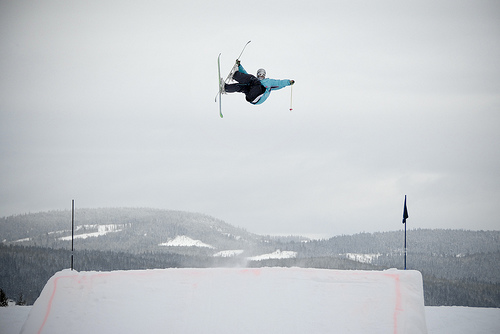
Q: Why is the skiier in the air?
A: Doing a trick.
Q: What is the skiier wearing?
A: Snow suit.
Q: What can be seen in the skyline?
A: Mountains.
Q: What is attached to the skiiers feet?
A: Snow skis.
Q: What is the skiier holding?
A: Ski poles.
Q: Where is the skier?
A: In the air.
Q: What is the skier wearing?
A: Blue.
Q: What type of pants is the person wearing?
A: Black.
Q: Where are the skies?
A: In the air.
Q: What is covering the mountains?
A: Snow.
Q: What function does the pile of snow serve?
A: Ski jump.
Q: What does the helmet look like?
A: Silver.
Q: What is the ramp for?
A: Doing jumps.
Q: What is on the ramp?
A: Red lines.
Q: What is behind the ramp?
A: Black poles.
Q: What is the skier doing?
A: Tricks.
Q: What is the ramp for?
A: Skier.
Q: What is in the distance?
A: Mountains.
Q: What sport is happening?
A: Skiing.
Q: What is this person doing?
A: Ski jumping.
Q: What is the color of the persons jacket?
A: Blue.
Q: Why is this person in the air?
A: Ski jumps.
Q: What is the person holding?
A: Ski poles.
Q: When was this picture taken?
A: Day time.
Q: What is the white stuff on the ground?
A: Snow.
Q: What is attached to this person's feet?
A: Skis.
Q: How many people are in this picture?
A: One.